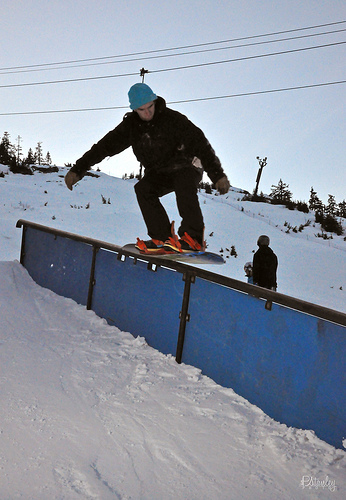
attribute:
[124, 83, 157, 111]
cap — green, knit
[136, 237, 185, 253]
strap — boot, snowboard, orange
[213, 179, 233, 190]
gloves — brown, ski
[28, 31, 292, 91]
cable — ski, chair, lift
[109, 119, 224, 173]
jacket — brown, dark, ski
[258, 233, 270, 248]
ski helmet — grey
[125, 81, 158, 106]
cap — blue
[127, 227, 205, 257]
snowboarding boots — orange, black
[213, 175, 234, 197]
ski glove — tan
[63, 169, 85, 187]
ski glove — tan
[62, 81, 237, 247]
snowboarder — trick-performing, rail trick-performing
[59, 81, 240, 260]
snowboarder — rail trick-performing